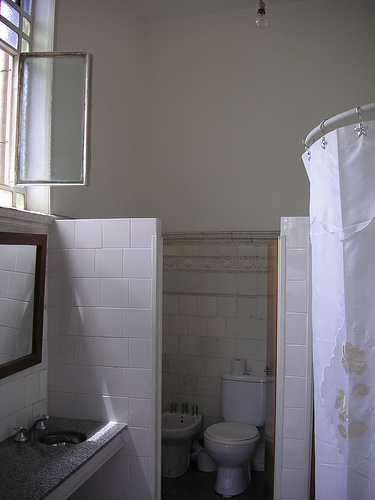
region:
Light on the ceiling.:
[245, 6, 279, 30]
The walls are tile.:
[52, 267, 168, 426]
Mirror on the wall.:
[2, 236, 58, 377]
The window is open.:
[1, 45, 84, 209]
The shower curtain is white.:
[302, 132, 373, 498]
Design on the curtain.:
[320, 343, 374, 464]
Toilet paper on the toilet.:
[224, 347, 249, 381]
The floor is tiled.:
[171, 465, 206, 498]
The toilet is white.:
[208, 423, 266, 496]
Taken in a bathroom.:
[8, 2, 371, 497]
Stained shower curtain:
[295, 131, 373, 431]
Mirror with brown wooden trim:
[2, 228, 81, 400]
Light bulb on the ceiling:
[242, 1, 294, 51]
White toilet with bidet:
[163, 356, 272, 480]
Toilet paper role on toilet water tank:
[219, 351, 255, 392]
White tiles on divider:
[64, 246, 155, 381]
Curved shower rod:
[289, 106, 374, 158]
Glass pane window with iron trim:
[1, 49, 95, 202]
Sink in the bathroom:
[10, 406, 103, 466]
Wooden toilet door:
[256, 241, 302, 494]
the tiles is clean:
[60, 275, 195, 495]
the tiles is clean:
[60, 241, 180, 387]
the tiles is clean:
[82, 271, 162, 431]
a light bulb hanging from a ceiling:
[244, 0, 273, 30]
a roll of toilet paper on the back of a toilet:
[225, 350, 245, 376]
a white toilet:
[196, 369, 274, 492]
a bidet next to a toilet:
[159, 397, 204, 477]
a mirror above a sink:
[0, 226, 49, 373]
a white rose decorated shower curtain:
[306, 129, 372, 497]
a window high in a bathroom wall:
[0, 3, 60, 207]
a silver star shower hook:
[351, 101, 371, 142]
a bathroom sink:
[33, 422, 90, 455]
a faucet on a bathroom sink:
[18, 409, 49, 445]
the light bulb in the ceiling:
[248, 0, 272, 30]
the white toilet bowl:
[201, 361, 263, 493]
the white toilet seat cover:
[205, 418, 256, 441]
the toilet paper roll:
[229, 354, 243, 372]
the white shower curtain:
[295, 133, 371, 497]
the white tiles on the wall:
[56, 230, 139, 396]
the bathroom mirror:
[5, 227, 47, 373]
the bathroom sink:
[38, 428, 88, 449]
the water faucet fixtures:
[14, 410, 46, 440]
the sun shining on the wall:
[86, 381, 121, 419]